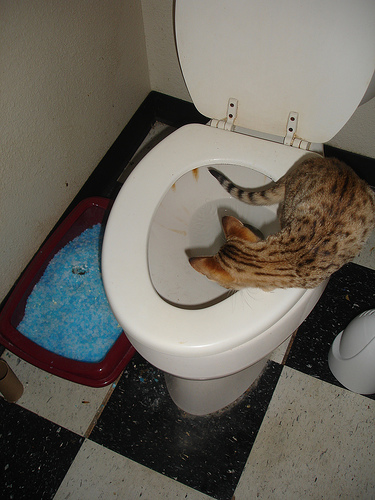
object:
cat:
[183, 153, 374, 297]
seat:
[97, 117, 342, 354]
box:
[1, 194, 138, 385]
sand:
[21, 218, 120, 359]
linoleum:
[4, 120, 374, 495]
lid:
[161, 0, 364, 153]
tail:
[207, 161, 293, 210]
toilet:
[100, 0, 374, 426]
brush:
[328, 309, 375, 401]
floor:
[3, 109, 369, 489]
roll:
[1, 354, 29, 401]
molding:
[88, 89, 375, 203]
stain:
[175, 169, 200, 192]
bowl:
[97, 116, 346, 411]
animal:
[188, 145, 373, 299]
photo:
[7, 11, 374, 490]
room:
[3, 0, 374, 498]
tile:
[50, 359, 283, 500]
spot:
[75, 397, 95, 412]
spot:
[300, 362, 315, 368]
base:
[155, 347, 278, 421]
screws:
[224, 90, 302, 137]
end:
[142, 6, 375, 134]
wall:
[170, 0, 374, 149]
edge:
[84, 90, 371, 204]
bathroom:
[6, 0, 374, 497]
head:
[189, 209, 264, 282]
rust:
[172, 163, 204, 194]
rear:
[179, 122, 332, 199]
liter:
[16, 219, 143, 355]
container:
[3, 190, 145, 358]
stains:
[169, 161, 204, 197]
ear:
[192, 249, 230, 286]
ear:
[220, 210, 256, 247]